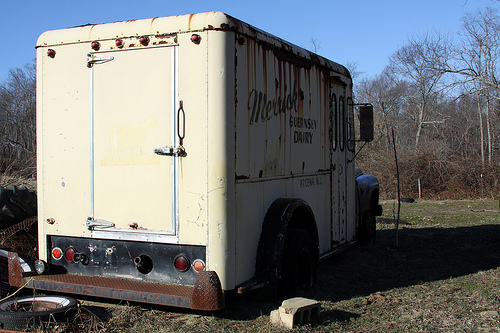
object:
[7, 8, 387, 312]
truck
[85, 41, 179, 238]
backdoor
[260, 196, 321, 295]
tires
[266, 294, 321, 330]
brick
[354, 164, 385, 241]
front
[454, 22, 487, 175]
trees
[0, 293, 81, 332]
tire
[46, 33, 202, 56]
light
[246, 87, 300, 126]
company's name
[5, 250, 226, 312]
bumper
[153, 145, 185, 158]
handle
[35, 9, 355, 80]
roof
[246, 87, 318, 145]
writing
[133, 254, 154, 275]
exhaust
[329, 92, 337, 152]
windows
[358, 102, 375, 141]
mirror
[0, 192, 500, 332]
ground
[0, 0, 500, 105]
sky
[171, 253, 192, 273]
light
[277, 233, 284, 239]
leaves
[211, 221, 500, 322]
shadow